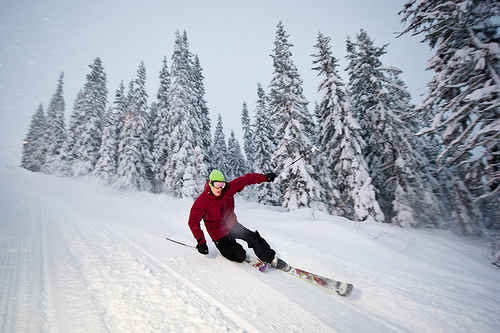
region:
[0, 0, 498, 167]
a large area of gray sky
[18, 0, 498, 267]
a large wooded area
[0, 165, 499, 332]
a snow covered ski slope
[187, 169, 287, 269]
a man skiing down the slope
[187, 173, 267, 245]
the man's red jacket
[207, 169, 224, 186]
the man's green hat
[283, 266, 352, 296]
the man's left ski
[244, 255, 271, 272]
the man's right ski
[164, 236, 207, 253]
the man's right pole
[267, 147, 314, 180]
the man's left pole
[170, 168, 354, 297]
a person skiing down a slope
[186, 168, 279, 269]
a person wearing a red jacket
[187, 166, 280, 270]
a person wearing a green cap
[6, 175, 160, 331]
ski tracks in the snow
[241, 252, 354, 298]
the skis on the snow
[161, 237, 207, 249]
the ski pole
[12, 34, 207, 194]
the trees with snow on them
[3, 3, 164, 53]
the blue sky in the background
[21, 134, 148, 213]
snow flipping up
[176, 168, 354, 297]
a person skiing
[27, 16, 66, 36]
white clouds in blue sky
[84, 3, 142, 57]
white clouds in blue sky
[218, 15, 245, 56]
white clouds in blue sky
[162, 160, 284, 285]
male skier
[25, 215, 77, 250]
white snow on hill side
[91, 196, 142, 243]
white snow on hill side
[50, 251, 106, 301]
white snow on hill side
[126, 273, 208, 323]
white snow on hill side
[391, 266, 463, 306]
white snow on hill side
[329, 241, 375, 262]
white snow on hill side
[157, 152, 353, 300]
a man on skies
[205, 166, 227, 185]
a man wearing a hat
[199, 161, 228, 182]
the hat is green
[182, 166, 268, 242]
the jacket is red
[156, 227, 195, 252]
the ski pole is on the ground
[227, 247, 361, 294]
the skies are long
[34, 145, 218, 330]
ski tracks on the snow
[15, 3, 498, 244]
fir trees behind the ski slope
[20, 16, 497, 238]
the trees are snow-covered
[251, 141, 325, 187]
this ski pole is in the air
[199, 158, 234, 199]
man has green hat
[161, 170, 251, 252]
man has red coat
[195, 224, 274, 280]
man has black pants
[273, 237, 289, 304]
man has black shoes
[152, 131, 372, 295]
man holds black poles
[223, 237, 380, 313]
man on white skis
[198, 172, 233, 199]
man is wearing goggles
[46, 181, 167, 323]
many tracks in snow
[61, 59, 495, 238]
snow covered evergreen trees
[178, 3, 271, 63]
sky is blue and white